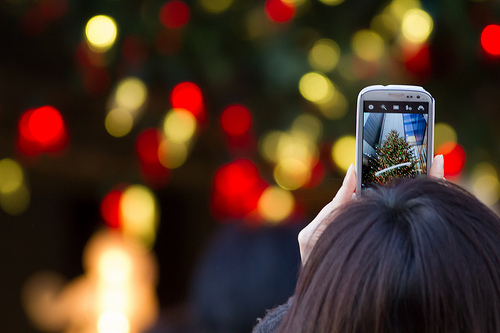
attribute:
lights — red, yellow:
[36, 49, 329, 264]